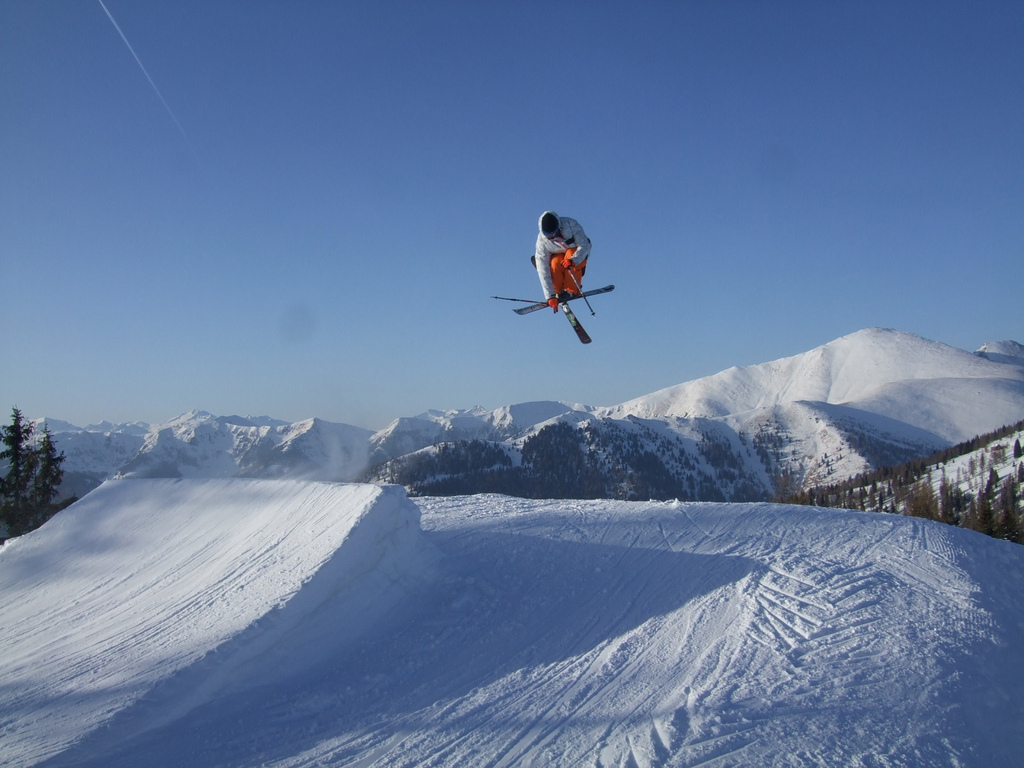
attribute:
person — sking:
[527, 203, 601, 325]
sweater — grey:
[531, 226, 598, 289]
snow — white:
[691, 620, 873, 713]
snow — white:
[732, 579, 877, 690]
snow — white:
[724, 538, 910, 742]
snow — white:
[635, 568, 716, 765]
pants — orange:
[542, 252, 586, 304]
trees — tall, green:
[2, 404, 76, 538]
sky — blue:
[121, 28, 988, 199]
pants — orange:
[539, 243, 587, 300]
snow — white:
[5, 454, 1023, 763]